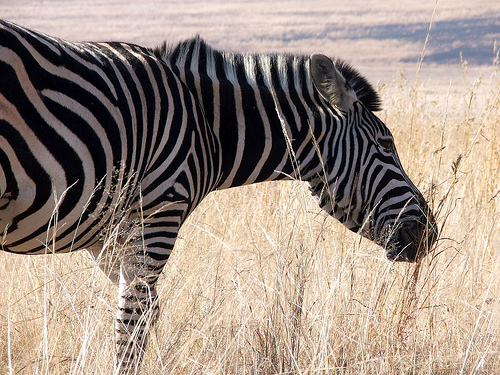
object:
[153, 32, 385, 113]
mane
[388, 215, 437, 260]
snout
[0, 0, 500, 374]
grass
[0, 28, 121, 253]
pattern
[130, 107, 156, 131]
fur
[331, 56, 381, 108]
hair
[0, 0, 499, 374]
field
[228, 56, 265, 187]
stripe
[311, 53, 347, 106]
ear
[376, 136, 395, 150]
eye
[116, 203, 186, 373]
leg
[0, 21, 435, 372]
zebra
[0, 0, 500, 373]
brush land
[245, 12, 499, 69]
shadow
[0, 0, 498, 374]
land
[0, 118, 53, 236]
stripes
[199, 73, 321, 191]
neck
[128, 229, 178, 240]
stripes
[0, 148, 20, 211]
stripes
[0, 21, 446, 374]
flank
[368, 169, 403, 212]
stripes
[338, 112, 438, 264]
face